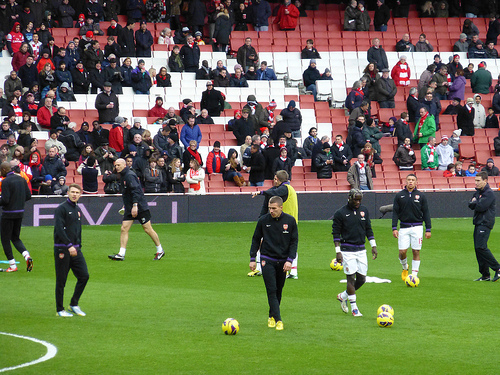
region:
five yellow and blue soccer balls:
[219, 256, 421, 336]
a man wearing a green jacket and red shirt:
[410, 107, 436, 147]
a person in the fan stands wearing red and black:
[205, 138, 225, 175]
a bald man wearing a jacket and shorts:
[110, 156, 165, 261]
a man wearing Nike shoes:
[106, 157, 165, 263]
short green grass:
[0, 215, 499, 371]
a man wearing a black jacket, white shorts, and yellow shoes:
[391, 173, 434, 287]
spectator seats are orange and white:
[0, 11, 496, 189]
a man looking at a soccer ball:
[218, 195, 297, 337]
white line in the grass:
[4, 329, 56, 374]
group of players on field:
[3, 171, 484, 312]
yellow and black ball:
[218, 312, 243, 344]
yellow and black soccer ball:
[207, 312, 248, 344]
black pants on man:
[252, 255, 299, 314]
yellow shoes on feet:
[258, 315, 286, 335]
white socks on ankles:
[113, 242, 168, 256]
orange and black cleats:
[18, 254, 33, 271]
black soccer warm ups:
[237, 215, 302, 310]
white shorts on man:
[341, 253, 367, 272]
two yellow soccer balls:
[365, 302, 405, 327]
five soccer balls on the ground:
[212, 253, 435, 358]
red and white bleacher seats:
[217, 26, 427, 111]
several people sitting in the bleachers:
[102, 26, 464, 181]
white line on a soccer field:
[0, 319, 91, 372]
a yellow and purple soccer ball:
[192, 299, 254, 347]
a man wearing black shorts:
[128, 197, 148, 239]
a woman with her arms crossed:
[185, 156, 205, 196]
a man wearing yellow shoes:
[264, 318, 294, 338]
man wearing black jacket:
[271, 235, 279, 250]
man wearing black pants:
[263, 274, 274, 295]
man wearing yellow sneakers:
[258, 319, 291, 333]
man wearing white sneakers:
[51, 305, 93, 323]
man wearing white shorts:
[346, 256, 361, 266]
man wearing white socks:
[411, 255, 416, 272]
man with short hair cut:
[479, 171, 487, 180]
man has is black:
[272, 197, 278, 202]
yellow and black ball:
[205, 305, 250, 350]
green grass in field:
[128, 314, 165, 346]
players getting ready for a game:
[15, 27, 488, 357]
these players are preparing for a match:
[23, 145, 495, 355]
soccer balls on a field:
[185, 299, 417, 348]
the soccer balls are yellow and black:
[181, 295, 266, 362]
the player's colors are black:
[215, 187, 323, 327]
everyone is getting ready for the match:
[28, 53, 493, 328]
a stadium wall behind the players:
[163, 185, 495, 232]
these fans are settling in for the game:
[28, 55, 454, 162]